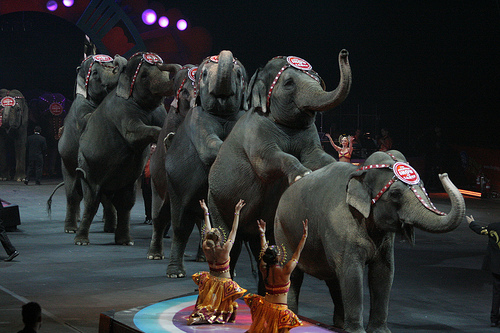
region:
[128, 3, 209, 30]
brightlights in the air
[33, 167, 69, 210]
wagging tail on elephant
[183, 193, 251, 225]
woman's arms in the air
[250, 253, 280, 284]
woman with long black plait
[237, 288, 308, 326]
woman wearing shimmering gold skirt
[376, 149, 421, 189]
red circle on front of elephant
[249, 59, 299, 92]
red and white circle on front of elephant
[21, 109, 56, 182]
man standing on the floor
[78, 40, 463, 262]
elephants lined up in a row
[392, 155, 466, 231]
elephant's tusk curled upwards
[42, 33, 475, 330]
the elephants are performing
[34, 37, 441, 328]
the elephants are gray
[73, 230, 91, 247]
large grey elephant foot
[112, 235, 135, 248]
large grey elephant foot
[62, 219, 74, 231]
large grey elephant foot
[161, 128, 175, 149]
large grey elephant foot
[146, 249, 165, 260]
large grey elephant foot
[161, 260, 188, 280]
large grey elephant foot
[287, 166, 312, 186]
large grey elephant foot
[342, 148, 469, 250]
large grey elephant head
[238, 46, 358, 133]
large grey elephant head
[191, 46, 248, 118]
large grey elephant head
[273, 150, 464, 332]
a grey elephant in the circus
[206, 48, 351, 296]
a grey elephant in the circus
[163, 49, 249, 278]
a grey elephant in the circus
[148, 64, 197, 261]
a grey elephant in the circus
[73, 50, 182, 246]
a grey elephant in the circus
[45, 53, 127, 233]
a grey elephant in the circus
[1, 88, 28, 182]
a grey elephant in the circus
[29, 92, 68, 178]
a grey elephant in the circus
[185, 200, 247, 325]
a woman wearing a yellow costume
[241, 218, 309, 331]
a woman wearing a yellow costume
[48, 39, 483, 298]
elephants in a circus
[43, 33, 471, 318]
elephants performing in a circus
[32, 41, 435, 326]
elephants heads decorated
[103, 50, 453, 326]
elephants standing on each other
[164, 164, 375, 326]
girls in a circus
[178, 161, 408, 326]
girls with their hair up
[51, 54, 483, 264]
elephants on each other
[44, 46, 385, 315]
elephants tanding inside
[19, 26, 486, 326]
elephants in a line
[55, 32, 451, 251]
elephants standing in a line